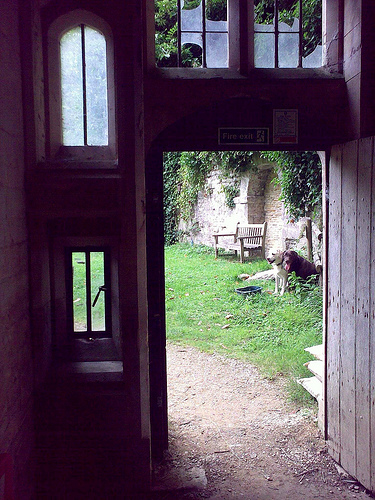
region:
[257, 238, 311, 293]
canines outside in green space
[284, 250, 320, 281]
dark canine in green space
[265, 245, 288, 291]
white canine in green space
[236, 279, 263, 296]
container in front of canines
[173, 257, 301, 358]
green space in outdoors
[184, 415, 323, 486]
sticks and rocks on ground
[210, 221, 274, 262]
bench in the outdoors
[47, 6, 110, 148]
arched window indoors of building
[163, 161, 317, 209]
green plants growing along wall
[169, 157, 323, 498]
doorway to the outdoors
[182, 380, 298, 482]
dirt path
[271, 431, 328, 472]
cluster of rocks on dirt path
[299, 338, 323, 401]
stack of bags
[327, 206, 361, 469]
structure made of wood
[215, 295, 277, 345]
patch of grass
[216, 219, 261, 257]
bench sitting alongside wall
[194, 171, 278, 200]
wall made of brick and stone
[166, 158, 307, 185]
overgrown ivies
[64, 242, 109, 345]
small window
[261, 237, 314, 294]
dogs sitting in grass with tongues out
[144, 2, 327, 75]
Broken glass in the windows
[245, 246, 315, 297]
There are two dogs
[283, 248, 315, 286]
The dog is brown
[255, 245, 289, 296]
The dog is white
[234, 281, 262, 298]
The square container is black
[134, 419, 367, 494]
There is dirt inside the building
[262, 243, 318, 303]
The dogs are in the grass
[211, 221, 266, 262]
The bench is by the wall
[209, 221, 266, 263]
The bench is brown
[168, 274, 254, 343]
Brown leaves on the grass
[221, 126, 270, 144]
The sign reads Fire Exit.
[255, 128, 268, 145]
A picture depicting a man running.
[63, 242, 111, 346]
A rectangular closed window.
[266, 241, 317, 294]
A black dog and White dog.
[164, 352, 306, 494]
A dirt path from the door.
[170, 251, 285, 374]
Green grassy terrain.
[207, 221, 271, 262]
A wooden bench on the grass.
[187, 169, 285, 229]
A wall made of brick.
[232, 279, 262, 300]
A bucket sitting in the grass.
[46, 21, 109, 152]
Sunlight coming through the window.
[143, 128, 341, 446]
doorway looking out on background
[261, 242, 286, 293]
white dog sitting in yard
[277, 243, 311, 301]
black dog sitting in yard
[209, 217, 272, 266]
wooden bench against wall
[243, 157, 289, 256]
recessed arch in brick wall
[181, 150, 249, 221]
hanging plants down side of wall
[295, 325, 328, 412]
wooden steps outside door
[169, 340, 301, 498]
dirt path leading in through door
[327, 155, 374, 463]
wooden board wall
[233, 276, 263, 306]
large blue dogs bowl